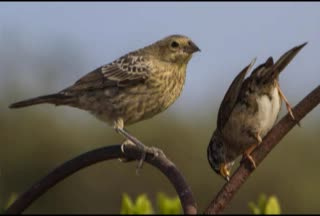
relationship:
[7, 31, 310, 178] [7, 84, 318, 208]
birds on branch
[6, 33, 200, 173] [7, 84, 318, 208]
bird on branch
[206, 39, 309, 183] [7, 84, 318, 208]
bird on branch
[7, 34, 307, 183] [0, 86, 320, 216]
birds in pole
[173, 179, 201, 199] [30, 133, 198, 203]
white spot on branch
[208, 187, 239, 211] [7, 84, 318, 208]
knob on branch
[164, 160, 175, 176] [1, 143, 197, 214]
knob on branch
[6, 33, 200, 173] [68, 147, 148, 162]
bird on branch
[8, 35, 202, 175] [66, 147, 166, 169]
bird standing on branch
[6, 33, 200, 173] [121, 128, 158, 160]
bird has leg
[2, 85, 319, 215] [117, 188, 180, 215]
plant has leaves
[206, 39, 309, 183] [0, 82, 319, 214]
bird on pole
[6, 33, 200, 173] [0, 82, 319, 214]
bird on pole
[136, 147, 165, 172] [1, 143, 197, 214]
claw on branch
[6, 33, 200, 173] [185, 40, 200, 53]
bird has beak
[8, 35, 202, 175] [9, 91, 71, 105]
bird has tail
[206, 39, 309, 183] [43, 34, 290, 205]
bird on branch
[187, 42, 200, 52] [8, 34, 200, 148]
beak of bird